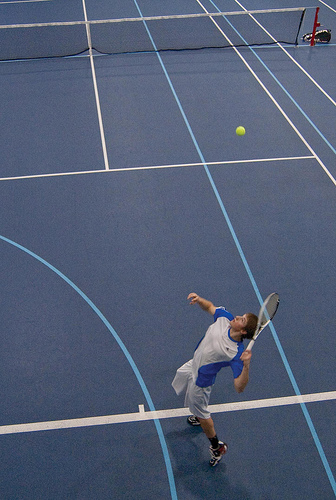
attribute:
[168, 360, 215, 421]
shorts — white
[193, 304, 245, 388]
shirt — white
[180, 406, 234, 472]
shoes — white, red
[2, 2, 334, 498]
tennis court — blue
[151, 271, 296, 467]
player — tennis